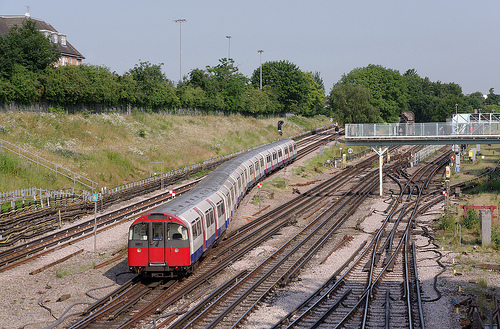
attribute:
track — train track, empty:
[69, 276, 210, 329]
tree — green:
[252, 60, 305, 117]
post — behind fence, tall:
[175, 18, 187, 87]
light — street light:
[175, 18, 186, 24]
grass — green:
[272, 177, 287, 190]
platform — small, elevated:
[341, 122, 499, 195]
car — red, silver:
[126, 196, 217, 285]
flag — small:
[256, 182, 263, 189]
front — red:
[128, 214, 191, 280]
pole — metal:
[57, 208, 63, 231]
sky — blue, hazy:
[1, 0, 499, 95]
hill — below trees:
[0, 105, 334, 217]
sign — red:
[459, 204, 495, 211]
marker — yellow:
[467, 150, 473, 159]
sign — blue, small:
[91, 193, 99, 203]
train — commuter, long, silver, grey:
[124, 138, 305, 270]